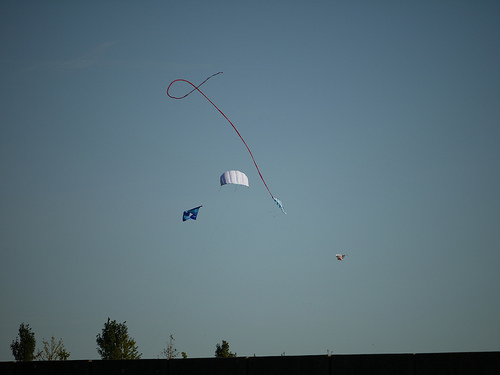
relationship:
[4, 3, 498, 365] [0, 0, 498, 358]
clouds in blue sky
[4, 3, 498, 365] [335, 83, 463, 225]
clouds in blue sky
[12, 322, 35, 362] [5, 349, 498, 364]
tree on horizon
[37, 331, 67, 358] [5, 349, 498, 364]
tree on horizon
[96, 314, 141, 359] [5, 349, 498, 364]
tree on horizon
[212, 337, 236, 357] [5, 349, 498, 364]
tree on horizon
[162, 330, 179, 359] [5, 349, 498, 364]
tree on horizon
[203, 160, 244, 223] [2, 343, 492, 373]
kite flying close to ground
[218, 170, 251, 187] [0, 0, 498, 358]
kite in blue sky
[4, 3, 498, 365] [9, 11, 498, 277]
clouds in sky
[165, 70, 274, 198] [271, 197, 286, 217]
red tail on kite